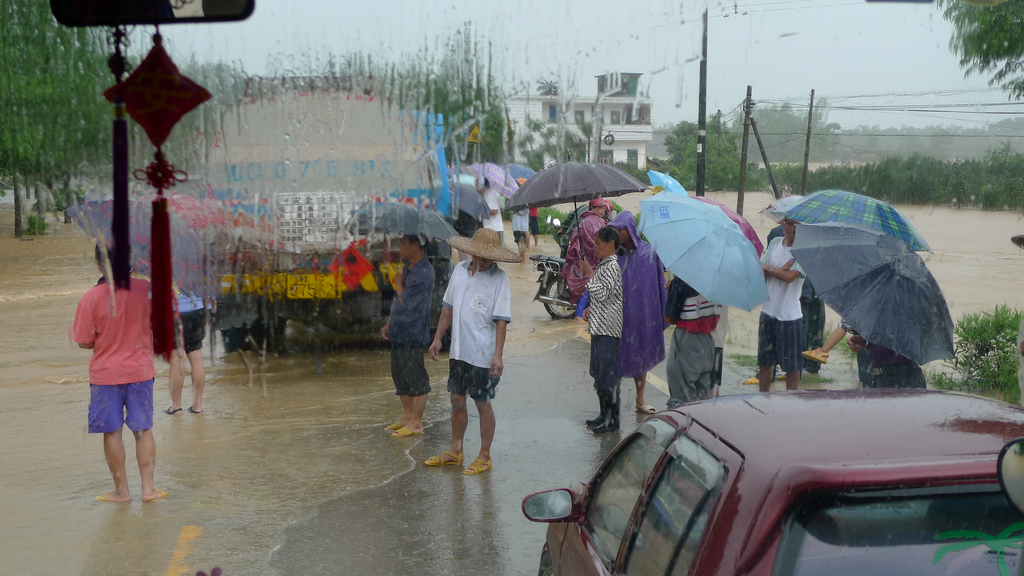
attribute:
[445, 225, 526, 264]
hat — large, straw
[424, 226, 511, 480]
man — standing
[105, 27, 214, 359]
item — hanging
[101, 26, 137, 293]
tassle — hanging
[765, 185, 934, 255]
umbrella — blue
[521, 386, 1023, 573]
vehicle — red, maroon, burgundy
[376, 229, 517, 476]
people — standing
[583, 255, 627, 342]
shirt — black, white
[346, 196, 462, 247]
umbrella — grey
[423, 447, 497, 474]
shoes — yellow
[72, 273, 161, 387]
shirt — pink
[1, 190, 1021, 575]
water — flooding, brown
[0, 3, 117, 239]
tree — green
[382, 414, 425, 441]
footwear — yellow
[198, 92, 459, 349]
bus — blue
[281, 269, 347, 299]
plate — yellow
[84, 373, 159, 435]
shorts — purple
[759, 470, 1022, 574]
windshield — large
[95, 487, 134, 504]
foot — bare